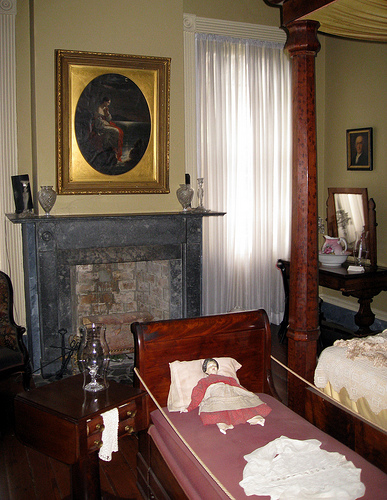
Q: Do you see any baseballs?
A: No, there are no baseballs.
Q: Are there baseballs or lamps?
A: No, there are no baseballs or lamps.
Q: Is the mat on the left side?
A: Yes, the mat is on the left of the image.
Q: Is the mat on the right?
A: No, the mat is on the left of the image.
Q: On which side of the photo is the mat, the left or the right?
A: The mat is on the left of the image.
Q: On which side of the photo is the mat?
A: The mat is on the left of the image.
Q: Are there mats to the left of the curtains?
A: Yes, there is a mat to the left of the curtains.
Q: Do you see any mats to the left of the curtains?
A: Yes, there is a mat to the left of the curtains.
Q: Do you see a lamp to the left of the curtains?
A: No, there is a mat to the left of the curtains.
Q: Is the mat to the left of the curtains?
A: Yes, the mat is to the left of the curtains.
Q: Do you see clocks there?
A: No, there are no clocks.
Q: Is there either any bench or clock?
A: No, there are no clocks or benches.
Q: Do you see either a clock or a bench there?
A: No, there are no clocks or benches.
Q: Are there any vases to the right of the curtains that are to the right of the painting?
A: Yes, there is a vase to the right of the curtains.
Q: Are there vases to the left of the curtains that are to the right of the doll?
A: No, the vase is to the right of the curtains.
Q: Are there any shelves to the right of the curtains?
A: No, there is a vase to the right of the curtains.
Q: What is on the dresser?
A: The vase is on the dresser.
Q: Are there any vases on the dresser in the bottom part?
A: Yes, there is a vase on the dresser.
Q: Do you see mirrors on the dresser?
A: No, there is a vase on the dresser.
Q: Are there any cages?
A: No, there are no cages.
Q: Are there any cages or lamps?
A: No, there are no cages or lamps.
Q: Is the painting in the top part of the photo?
A: Yes, the painting is in the top of the image.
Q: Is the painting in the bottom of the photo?
A: No, the painting is in the top of the image.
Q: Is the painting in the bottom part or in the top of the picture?
A: The painting is in the top of the image.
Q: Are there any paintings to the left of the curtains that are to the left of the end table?
A: Yes, there is a painting to the left of the curtains.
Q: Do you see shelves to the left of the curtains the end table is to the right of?
A: No, there is a painting to the left of the curtains.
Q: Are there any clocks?
A: No, there are no clocks.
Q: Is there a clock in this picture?
A: No, there are no clocks.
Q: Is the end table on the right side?
A: Yes, the end table is on the right of the image.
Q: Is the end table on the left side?
A: No, the end table is on the right of the image.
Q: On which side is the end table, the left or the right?
A: The end table is on the right of the image.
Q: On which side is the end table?
A: The end table is on the right of the image.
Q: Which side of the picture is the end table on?
A: The end table is on the right of the image.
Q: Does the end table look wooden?
A: Yes, the end table is wooden.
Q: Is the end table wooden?
A: Yes, the end table is wooden.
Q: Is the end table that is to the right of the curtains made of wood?
A: Yes, the end table is made of wood.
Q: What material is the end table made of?
A: The end table is made of wood.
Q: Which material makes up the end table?
A: The end table is made of wood.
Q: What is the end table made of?
A: The end table is made of wood.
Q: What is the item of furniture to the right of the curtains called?
A: The piece of furniture is an end table.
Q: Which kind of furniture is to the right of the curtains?
A: The piece of furniture is an end table.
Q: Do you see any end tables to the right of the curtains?
A: Yes, there is an end table to the right of the curtains.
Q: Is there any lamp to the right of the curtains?
A: No, there is an end table to the right of the curtains.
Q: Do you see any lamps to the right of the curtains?
A: No, there is an end table to the right of the curtains.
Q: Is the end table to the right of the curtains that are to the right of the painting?
A: Yes, the end table is to the right of the curtains.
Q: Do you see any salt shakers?
A: No, there are no salt shakers.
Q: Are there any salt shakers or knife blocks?
A: No, there are no salt shakers or knife blocks.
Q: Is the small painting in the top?
A: Yes, the painting is in the top of the image.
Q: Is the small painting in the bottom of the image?
A: No, the painting is in the top of the image.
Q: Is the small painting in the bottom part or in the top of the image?
A: The painting is in the top of the image.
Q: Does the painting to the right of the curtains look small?
A: Yes, the painting is small.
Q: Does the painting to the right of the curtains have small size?
A: Yes, the painting is small.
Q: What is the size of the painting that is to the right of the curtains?
A: The painting is small.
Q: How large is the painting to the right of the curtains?
A: The painting is small.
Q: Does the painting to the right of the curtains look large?
A: No, the painting is small.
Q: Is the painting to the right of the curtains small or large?
A: The painting is small.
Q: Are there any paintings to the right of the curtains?
A: Yes, there is a painting to the right of the curtains.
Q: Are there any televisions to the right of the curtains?
A: No, there is a painting to the right of the curtains.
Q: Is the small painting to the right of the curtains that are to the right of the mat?
A: Yes, the painting is to the right of the curtains.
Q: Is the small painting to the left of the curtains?
A: No, the painting is to the right of the curtains.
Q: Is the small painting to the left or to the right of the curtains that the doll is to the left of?
A: The painting is to the right of the curtains.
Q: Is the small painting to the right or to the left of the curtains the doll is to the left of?
A: The painting is to the right of the curtains.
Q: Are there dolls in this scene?
A: Yes, there is a doll.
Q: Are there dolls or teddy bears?
A: Yes, there is a doll.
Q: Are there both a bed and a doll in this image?
A: Yes, there are both a doll and a bed.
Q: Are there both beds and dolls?
A: Yes, there are both a doll and a bed.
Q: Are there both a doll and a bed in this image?
A: Yes, there are both a doll and a bed.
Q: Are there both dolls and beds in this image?
A: Yes, there are both a doll and a bed.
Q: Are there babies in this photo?
A: No, there are no babies.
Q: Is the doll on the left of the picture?
A: Yes, the doll is on the left of the image.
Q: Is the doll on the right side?
A: No, the doll is on the left of the image.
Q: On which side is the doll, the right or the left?
A: The doll is on the left of the image.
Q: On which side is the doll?
A: The doll is on the left of the image.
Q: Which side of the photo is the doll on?
A: The doll is on the left of the image.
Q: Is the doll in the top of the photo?
A: Yes, the doll is in the top of the image.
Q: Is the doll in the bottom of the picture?
A: No, the doll is in the top of the image.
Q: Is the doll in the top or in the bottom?
A: The doll is in the top of the image.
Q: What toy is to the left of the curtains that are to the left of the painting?
A: The toy is a doll.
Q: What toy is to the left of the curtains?
A: The toy is a doll.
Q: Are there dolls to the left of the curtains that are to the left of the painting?
A: Yes, there is a doll to the left of the curtains.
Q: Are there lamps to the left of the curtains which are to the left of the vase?
A: No, there is a doll to the left of the curtains.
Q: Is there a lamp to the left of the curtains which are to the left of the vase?
A: No, there is a doll to the left of the curtains.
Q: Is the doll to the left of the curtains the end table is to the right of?
A: Yes, the doll is to the left of the curtains.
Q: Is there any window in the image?
A: Yes, there is a window.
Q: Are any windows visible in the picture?
A: Yes, there is a window.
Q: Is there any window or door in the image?
A: Yes, there is a window.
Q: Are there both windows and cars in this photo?
A: No, there is a window but no cars.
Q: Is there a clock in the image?
A: No, there are no clocks.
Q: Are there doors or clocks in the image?
A: No, there are no clocks or doors.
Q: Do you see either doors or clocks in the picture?
A: No, there are no clocks or doors.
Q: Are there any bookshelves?
A: No, there are no bookshelves.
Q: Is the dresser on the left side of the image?
A: Yes, the dresser is on the left of the image.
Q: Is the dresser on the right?
A: No, the dresser is on the left of the image.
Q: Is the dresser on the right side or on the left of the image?
A: The dresser is on the left of the image.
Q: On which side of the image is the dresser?
A: The dresser is on the left of the image.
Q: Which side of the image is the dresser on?
A: The dresser is on the left of the image.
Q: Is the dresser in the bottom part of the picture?
A: Yes, the dresser is in the bottom of the image.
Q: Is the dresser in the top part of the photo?
A: No, the dresser is in the bottom of the image.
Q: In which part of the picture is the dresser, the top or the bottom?
A: The dresser is in the bottom of the image.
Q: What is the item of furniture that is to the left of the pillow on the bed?
A: The piece of furniture is a dresser.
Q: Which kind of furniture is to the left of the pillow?
A: The piece of furniture is a dresser.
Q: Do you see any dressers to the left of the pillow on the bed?
A: Yes, there is a dresser to the left of the pillow.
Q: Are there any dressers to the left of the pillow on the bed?
A: Yes, there is a dresser to the left of the pillow.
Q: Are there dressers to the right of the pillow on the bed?
A: No, the dresser is to the left of the pillow.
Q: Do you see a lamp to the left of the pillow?
A: No, there is a dresser to the left of the pillow.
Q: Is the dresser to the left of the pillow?
A: Yes, the dresser is to the left of the pillow.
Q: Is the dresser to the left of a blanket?
A: No, the dresser is to the left of the pillow.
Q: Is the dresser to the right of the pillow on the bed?
A: No, the dresser is to the left of the pillow.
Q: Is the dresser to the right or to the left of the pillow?
A: The dresser is to the left of the pillow.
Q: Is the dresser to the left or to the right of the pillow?
A: The dresser is to the left of the pillow.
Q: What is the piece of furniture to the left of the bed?
A: The piece of furniture is a dresser.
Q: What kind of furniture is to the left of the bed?
A: The piece of furniture is a dresser.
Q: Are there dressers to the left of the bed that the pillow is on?
A: Yes, there is a dresser to the left of the bed.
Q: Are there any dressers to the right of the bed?
A: No, the dresser is to the left of the bed.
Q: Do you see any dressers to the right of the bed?
A: No, the dresser is to the left of the bed.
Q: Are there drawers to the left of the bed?
A: No, there is a dresser to the left of the bed.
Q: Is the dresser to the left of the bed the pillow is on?
A: Yes, the dresser is to the left of the bed.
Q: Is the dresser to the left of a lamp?
A: No, the dresser is to the left of the bed.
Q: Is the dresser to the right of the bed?
A: No, the dresser is to the left of the bed.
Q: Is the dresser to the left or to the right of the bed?
A: The dresser is to the left of the bed.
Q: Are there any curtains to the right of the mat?
A: Yes, there are curtains to the right of the mat.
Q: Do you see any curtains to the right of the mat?
A: Yes, there are curtains to the right of the mat.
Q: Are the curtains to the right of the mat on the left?
A: Yes, the curtains are to the right of the mat.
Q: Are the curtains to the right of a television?
A: No, the curtains are to the right of the mat.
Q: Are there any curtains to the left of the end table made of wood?
A: Yes, there are curtains to the left of the end table.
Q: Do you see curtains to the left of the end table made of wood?
A: Yes, there are curtains to the left of the end table.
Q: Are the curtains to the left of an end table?
A: Yes, the curtains are to the left of an end table.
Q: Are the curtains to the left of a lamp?
A: No, the curtains are to the left of an end table.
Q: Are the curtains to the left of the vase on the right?
A: Yes, the curtains are to the left of the vase.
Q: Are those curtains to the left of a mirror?
A: No, the curtains are to the left of the vase.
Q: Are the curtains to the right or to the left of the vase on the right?
A: The curtains are to the left of the vase.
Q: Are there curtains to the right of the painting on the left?
A: Yes, there are curtains to the right of the painting.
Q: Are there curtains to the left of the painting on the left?
A: No, the curtains are to the right of the painting.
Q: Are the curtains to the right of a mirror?
A: No, the curtains are to the right of a painting.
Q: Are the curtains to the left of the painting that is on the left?
A: No, the curtains are to the right of the painting.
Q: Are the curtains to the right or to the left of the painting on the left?
A: The curtains are to the right of the painting.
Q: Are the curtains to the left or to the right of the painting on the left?
A: The curtains are to the right of the painting.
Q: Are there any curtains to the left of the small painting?
A: Yes, there are curtains to the left of the painting.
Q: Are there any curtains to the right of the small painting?
A: No, the curtains are to the left of the painting.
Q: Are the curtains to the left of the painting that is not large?
A: Yes, the curtains are to the left of the painting.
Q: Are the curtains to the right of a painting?
A: No, the curtains are to the left of a painting.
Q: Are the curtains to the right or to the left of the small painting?
A: The curtains are to the left of the painting.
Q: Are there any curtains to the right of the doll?
A: Yes, there are curtains to the right of the doll.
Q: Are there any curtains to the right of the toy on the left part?
A: Yes, there are curtains to the right of the doll.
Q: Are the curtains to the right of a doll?
A: Yes, the curtains are to the right of a doll.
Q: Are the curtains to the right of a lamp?
A: No, the curtains are to the right of a doll.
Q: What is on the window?
A: The curtains are on the window.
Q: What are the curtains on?
A: The curtains are on the window.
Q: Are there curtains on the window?
A: Yes, there are curtains on the window.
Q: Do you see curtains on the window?
A: Yes, there are curtains on the window.